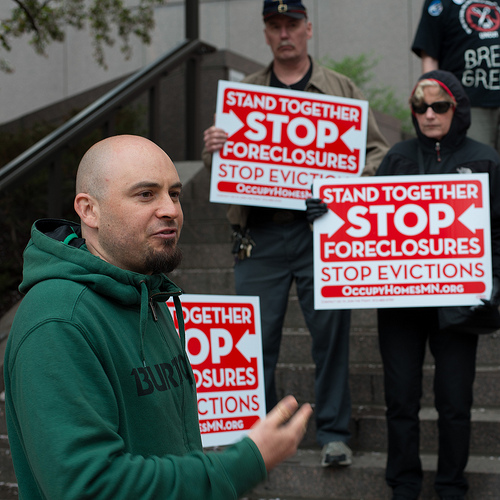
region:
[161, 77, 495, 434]
three bright red and white signs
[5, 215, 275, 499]
man wearing a large green Burton sweater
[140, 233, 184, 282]
man has a goatee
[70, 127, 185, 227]
man has a bald head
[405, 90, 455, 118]
woman wearing dark sunglasses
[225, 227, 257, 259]
keys hanging off man's pants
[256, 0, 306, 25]
man wearing a black hat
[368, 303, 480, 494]
woman wearing black pants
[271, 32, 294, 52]
man has a moustache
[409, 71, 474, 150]
woman wearing a hood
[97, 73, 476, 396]
people standing together outside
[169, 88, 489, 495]
people standing on the stairs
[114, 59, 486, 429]
people that are protesting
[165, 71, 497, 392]
protestors that are holding signs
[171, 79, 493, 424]
people protester foreclosure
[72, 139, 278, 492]
a man wearing a hoodie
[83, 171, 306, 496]
a man wearing a green hoodie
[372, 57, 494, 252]
a woman wearing sunglasses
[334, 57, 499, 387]
a woman wearing jacket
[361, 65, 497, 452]
a woman wearing a black jacket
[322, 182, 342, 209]
White lettering on a whtie and red sign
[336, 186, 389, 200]
White lettering on a whtie and red sign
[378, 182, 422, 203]
White lettering on a whtie and red sign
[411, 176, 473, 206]
White lettering on a whtie and red sign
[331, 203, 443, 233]
White lettering on a whtie and red sign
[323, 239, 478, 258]
White lettering on a whtie and red sign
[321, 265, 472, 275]
White lettering on a whtie and red sign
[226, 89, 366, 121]
White lettering on a whtie and red sign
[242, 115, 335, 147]
White lettering on a whtie and red sign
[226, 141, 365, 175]
White lettering on a whtie and red sign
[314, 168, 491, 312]
Red and white sign.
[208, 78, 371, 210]
A red protest sign.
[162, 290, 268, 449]
A large red and white sign.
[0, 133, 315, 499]
A bald white male.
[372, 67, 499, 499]
A woman in a hood.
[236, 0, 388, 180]
A man wearing a hat.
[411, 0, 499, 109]
A black colored shirt.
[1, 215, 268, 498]
A green colored hoodie.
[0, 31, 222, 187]
A gray stair railing.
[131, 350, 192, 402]
Black letters on green.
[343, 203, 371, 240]
one white capital letter S on red background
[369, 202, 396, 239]
one white capital letter T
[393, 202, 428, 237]
one white capital letter O on red background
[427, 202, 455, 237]
one white capital letter P on red background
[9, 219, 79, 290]
one green sweatshirt hood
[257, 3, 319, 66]
one man wearing black baseball cap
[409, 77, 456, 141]
woman wearing dark sunglasses